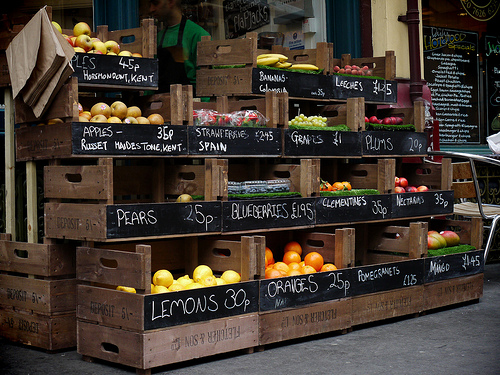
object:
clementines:
[320, 177, 352, 192]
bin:
[76, 236, 258, 370]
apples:
[78, 101, 164, 124]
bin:
[277, 92, 363, 159]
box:
[325, 217, 432, 329]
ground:
[395, 176, 429, 193]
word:
[152, 294, 219, 321]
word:
[268, 275, 319, 298]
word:
[358, 266, 401, 282]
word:
[430, 259, 450, 275]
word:
[117, 209, 158, 227]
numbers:
[224, 289, 246, 310]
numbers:
[327, 272, 344, 290]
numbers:
[184, 204, 206, 224]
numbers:
[297, 203, 313, 220]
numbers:
[372, 200, 383, 215]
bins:
[8, 6, 159, 93]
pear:
[176, 194, 194, 202]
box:
[299, 222, 425, 299]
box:
[368, 218, 485, 286]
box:
[390, 157, 454, 221]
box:
[282, 157, 392, 226]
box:
[216, 156, 316, 235]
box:
[44, 159, 221, 242]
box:
[15, 75, 189, 162]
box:
[162, 87, 280, 162]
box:
[229, 92, 361, 157]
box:
[357, 97, 430, 157]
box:
[283, 42, 398, 103]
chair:
[423, 149, 500, 281]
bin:
[206, 222, 352, 315]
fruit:
[265, 241, 338, 279]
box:
[164, 159, 316, 232]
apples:
[51, 21, 143, 58]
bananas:
[257, 54, 319, 71]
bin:
[195, 32, 329, 102]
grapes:
[288, 114, 328, 128]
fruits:
[396, 230, 461, 250]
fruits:
[117, 264, 242, 294]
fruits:
[228, 179, 291, 194]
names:
[81, 126, 182, 153]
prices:
[291, 202, 314, 220]